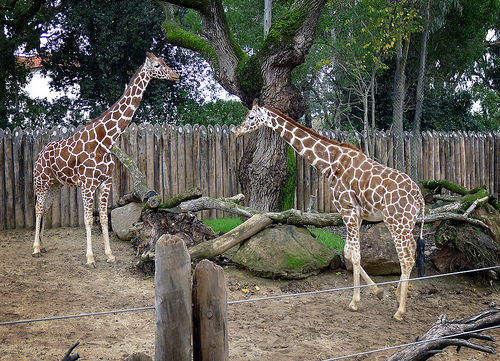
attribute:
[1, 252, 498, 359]
sand — ground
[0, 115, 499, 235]
fence — wooden, brown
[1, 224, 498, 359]
sand — brown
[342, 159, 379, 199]
fur — brown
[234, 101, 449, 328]
giraffe — brown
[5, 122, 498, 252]
fence — brown, wooden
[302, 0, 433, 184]
trees — tall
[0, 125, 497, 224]
fence — wood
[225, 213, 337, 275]
rock — moss covered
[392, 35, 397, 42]
leaf — green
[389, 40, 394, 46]
leaf — green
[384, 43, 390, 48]
leaf — green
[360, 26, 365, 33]
leaf — green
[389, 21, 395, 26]
leaf — green